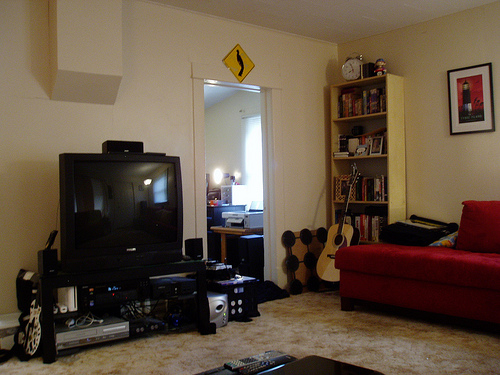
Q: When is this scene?
A: Daytime.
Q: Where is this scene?
A: Living room.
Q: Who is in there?
A: No one.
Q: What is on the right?
A: TV.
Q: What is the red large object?
A: Couch.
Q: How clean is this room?
A: Very tidy.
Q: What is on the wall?
A: Picture.